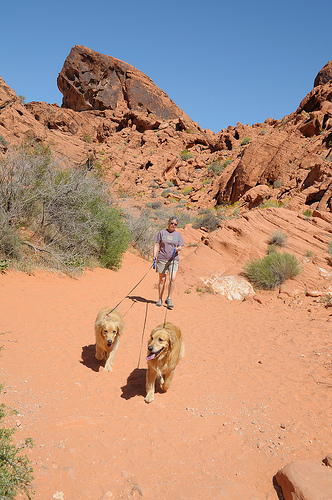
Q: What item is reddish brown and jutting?
A: A rock.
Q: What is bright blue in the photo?
A: Sky.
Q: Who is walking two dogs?
A: Lady.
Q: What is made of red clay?
A: Ground.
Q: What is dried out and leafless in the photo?
A: Bushes.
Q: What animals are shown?
A: Two dogs.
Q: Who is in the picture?
A: A man.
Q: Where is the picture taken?
A: The desert.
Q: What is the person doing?
A: Walking two dogs.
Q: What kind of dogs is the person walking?
A: Golden retrievers.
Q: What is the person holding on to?
A: Two leashes.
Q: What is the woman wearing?
A: A t-shirt and shorts.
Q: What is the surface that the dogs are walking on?
A: Sand.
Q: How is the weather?
A: Clear.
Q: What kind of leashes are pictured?
A: Retractable leashes.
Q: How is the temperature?
A: Hot.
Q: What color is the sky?
A: Blue.